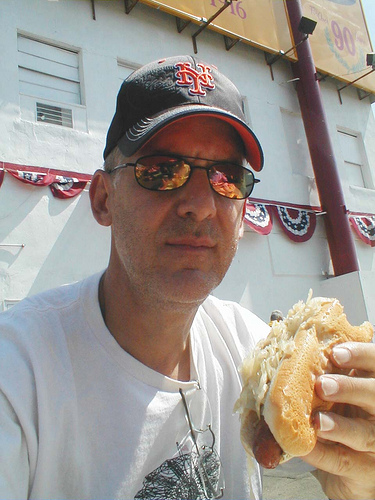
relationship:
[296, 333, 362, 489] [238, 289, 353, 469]
hand in bun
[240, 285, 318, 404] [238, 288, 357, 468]
saurkraut on hot dog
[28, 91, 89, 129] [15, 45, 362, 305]
conditioner in wall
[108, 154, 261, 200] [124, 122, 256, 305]
sunglasses on face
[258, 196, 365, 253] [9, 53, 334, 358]
banner on wall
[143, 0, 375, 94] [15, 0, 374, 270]
billboard on wall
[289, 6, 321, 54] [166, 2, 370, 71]
light by billboard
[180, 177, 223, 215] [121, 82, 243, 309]
nose on man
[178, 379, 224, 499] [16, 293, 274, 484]
eyeglasses on shirt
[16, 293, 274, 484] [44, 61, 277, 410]
shirt on man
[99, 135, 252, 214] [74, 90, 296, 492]
sunglasses on man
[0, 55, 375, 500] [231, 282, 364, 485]
man with hotdog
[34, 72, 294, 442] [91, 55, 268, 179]
man with hat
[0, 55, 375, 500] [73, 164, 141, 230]
man with ear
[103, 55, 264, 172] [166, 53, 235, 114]
cap with logo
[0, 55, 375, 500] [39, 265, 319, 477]
man with shirt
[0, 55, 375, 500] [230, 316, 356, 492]
man with hotdog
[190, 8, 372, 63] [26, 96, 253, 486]
billboard above man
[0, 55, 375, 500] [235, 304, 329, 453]
man with hotdog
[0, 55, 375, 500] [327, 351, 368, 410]
man with hand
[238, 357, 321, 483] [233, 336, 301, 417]
hot dog with sauerkraut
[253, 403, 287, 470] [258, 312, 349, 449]
hot dog with bun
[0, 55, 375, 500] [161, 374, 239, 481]
man with eyeglasses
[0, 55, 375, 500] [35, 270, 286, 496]
man with shirt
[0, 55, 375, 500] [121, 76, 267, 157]
man with cap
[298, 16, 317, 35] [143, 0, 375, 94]
light below billboard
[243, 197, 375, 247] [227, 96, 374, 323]
banner on back wall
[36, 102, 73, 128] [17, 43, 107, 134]
conditioner over window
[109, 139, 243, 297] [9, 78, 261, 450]
head on person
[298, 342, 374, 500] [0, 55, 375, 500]
hand on man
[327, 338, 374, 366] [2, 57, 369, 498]
finger on person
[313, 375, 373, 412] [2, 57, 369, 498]
finger on person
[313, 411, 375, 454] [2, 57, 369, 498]
finger on person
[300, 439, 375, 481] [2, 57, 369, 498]
finger on person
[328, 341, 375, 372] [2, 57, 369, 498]
finger on person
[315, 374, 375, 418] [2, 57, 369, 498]
finger on person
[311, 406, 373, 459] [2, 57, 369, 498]
finger on person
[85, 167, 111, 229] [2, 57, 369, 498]
ear on person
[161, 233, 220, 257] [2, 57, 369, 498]
mouth on person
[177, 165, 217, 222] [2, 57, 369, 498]
nose of a person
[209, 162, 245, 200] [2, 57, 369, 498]
eye of a person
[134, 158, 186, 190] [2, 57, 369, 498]
eye of a person